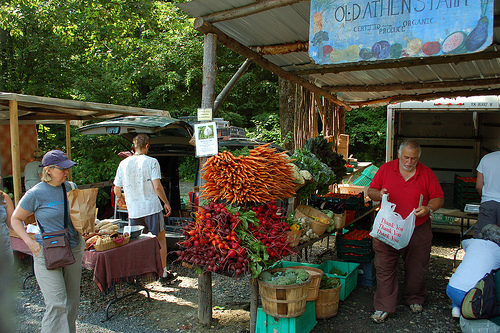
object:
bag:
[36, 182, 76, 271]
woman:
[10, 147, 87, 332]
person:
[446, 223, 500, 318]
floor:
[18, 264, 463, 333]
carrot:
[199, 142, 297, 203]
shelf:
[239, 162, 377, 333]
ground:
[23, 285, 259, 332]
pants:
[32, 239, 84, 332]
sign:
[306, 0, 497, 67]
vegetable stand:
[174, 134, 379, 291]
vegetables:
[200, 153, 291, 241]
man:
[112, 133, 178, 282]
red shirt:
[367, 157, 443, 227]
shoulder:
[29, 181, 77, 193]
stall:
[216, 2, 498, 324]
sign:
[192, 108, 218, 158]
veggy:
[202, 148, 299, 207]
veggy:
[296, 163, 331, 196]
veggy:
[316, 143, 351, 169]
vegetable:
[259, 268, 308, 285]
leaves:
[0, 0, 204, 110]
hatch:
[73, 115, 195, 138]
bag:
[66, 186, 97, 235]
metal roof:
[225, 11, 307, 44]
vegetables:
[258, 268, 308, 284]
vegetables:
[240, 238, 276, 254]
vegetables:
[320, 269, 339, 289]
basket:
[256, 268, 311, 318]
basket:
[280, 265, 323, 302]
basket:
[314, 276, 343, 321]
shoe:
[371, 310, 389, 324]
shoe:
[410, 303, 425, 313]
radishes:
[173, 202, 299, 279]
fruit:
[258, 269, 309, 285]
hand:
[413, 206, 430, 218]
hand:
[379, 188, 390, 200]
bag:
[371, 192, 418, 252]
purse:
[40, 228, 77, 271]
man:
[367, 139, 444, 323]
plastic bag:
[368, 193, 417, 250]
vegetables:
[179, 131, 373, 290]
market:
[0, 104, 499, 333]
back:
[121, 156, 154, 206]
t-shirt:
[112, 155, 163, 220]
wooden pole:
[197, 19, 215, 324]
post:
[195, 34, 220, 325]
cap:
[42, 149, 77, 169]